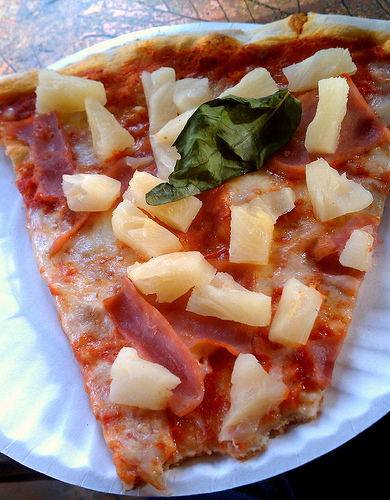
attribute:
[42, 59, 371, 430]
pineapple — chunky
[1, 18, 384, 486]
pizza — large, bitten, half eaten, sliced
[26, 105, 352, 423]
bacon — cooked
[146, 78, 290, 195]
leaf — green, wilted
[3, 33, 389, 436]
sauce — red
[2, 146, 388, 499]
paper plate — white, edged, ridged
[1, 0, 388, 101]
crust — white, burnt, dry, thin, pale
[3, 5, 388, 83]
countertop — designed, brown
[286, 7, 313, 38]
spot — brown